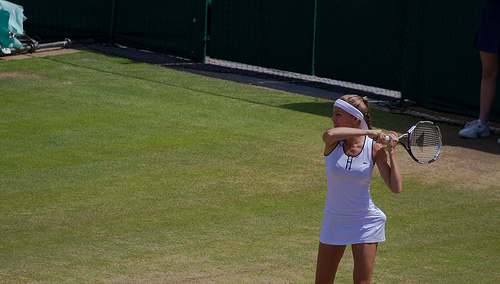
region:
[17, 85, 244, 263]
green turf of the tennis court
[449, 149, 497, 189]
dirt in the tennis court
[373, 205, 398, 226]
tennis ball in shorts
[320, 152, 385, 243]
white female tennis outfit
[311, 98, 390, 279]
pretty female tennis player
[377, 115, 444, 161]
white and black tennis racket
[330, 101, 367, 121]
white sweat band on the head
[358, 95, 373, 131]
blonde hair in a pony tail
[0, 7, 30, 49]
green plastic covering for something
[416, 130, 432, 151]
wire frame of the tennis racket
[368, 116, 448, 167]
tennis racket in players hands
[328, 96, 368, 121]
woman wearing white headband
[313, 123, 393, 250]
woman wearing tennis whites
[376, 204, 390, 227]
tennis ball inside players pocket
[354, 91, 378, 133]
woman's hair in braid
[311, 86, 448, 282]
tennis player is swinging racket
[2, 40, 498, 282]
tennis court is green grass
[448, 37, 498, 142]
ball girl leg against wall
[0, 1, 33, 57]
green tarp in corner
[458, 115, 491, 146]
woman wearing white sneaker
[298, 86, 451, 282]
Woman is in the foreground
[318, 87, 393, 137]
Woman is wearing a sweatband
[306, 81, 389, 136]
The sweatband is white in color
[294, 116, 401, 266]
Woman is wearing a sports dress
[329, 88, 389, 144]
Woman has blonde hair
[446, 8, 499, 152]
Person's leg is in view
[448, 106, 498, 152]
Person is wearing white shoes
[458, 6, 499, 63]
Person is wearing shorts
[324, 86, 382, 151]
Side view of a woman's head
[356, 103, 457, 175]
Woman is holding a tennis racquet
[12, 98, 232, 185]
green grass on a tennis court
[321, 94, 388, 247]
tennis player wearing a white dress and a white sweatband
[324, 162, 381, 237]
woman's white tennis dress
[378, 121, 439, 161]
tennis racket in the young woman's hands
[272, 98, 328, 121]
shadows being cast from the sun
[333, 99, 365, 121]
white headband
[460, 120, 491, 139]
white tennis shoe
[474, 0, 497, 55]
woman's blue skirt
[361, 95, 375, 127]
braid in the young woman's hair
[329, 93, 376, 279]
young woman playing tennis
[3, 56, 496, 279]
Part of a grass tennis court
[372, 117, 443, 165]
tennis racket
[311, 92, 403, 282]
female tennis player in white tennis dress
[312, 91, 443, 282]
Tennis player swinging racket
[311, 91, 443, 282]
Tennis player with two hands on racket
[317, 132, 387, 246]
white tennis dress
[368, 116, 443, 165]
tennis racket being held by tennis player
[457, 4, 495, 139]
Right leg of a person